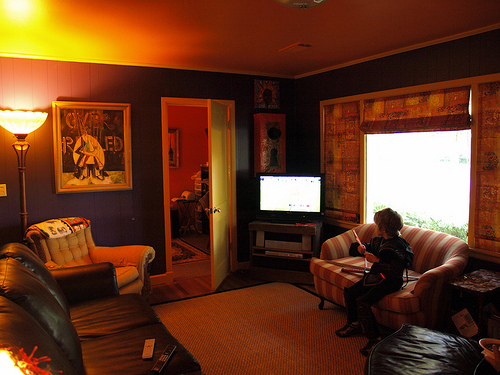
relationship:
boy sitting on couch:
[335, 208, 413, 355] [302, 179, 482, 291]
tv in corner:
[238, 147, 361, 242] [215, 61, 330, 299]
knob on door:
[202, 203, 221, 218] [208, 104, 235, 286]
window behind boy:
[361, 128, 472, 246] [343, 199, 420, 309]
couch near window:
[309, 223, 471, 331] [366, 137, 468, 217]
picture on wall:
[48, 96, 138, 196] [48, 192, 169, 230]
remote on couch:
[142, 339, 156, 359] [296, 225, 471, 342]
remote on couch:
[150, 344, 178, 374] [296, 225, 471, 342]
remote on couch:
[142, 339, 156, 359] [0, 236, 206, 373]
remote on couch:
[140, 337, 176, 372] [0, 236, 206, 373]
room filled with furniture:
[13, 21, 489, 350] [3, 191, 203, 301]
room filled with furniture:
[13, 21, 489, 350] [10, 262, 141, 366]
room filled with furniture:
[13, 21, 489, 350] [400, 236, 450, 300]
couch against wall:
[310, 168, 487, 333] [320, 109, 368, 226]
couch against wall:
[0, 236, 206, 373] [2, 152, 23, 243]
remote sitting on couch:
[142, 335, 154, 362] [0, 236, 206, 373]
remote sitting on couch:
[150, 344, 178, 374] [0, 236, 206, 373]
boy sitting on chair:
[354, 204, 434, 346] [308, 217, 470, 337]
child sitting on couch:
[334, 204, 416, 340] [306, 212, 480, 339]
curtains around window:
[315, 72, 498, 253] [359, 128, 471, 247]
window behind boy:
[365, 130, 471, 242] [340, 208, 410, 355]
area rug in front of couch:
[156, 280, 381, 373] [309, 223, 471, 331]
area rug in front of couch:
[156, 280, 381, 373] [0, 236, 206, 373]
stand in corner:
[242, 216, 309, 257] [244, 79, 388, 266]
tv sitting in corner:
[258, 170, 323, 218] [215, 117, 348, 261]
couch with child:
[309, 223, 471, 331] [334, 205, 415, 355]